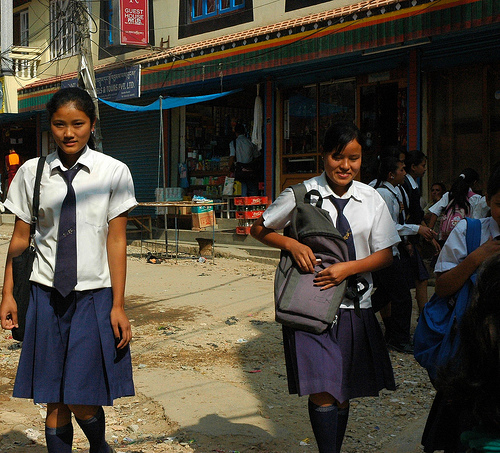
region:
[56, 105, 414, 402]
Children in school uniforms.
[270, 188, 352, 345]
Girl carrying her backpack.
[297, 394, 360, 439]
The girl is wearing blue socks.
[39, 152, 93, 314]
Girl is wearing a blue tie.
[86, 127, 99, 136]
The girl is wearing earring.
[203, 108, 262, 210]
A person standingin the store.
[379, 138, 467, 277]
A group of kids by the building.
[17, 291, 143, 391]
The skirt uniform is blue.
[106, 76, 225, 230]
An umbrella over the table.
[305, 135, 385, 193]
The girl is smiling.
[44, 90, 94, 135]
girl has dark hair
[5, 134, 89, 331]
black bag around shoulder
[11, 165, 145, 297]
girl has white shirt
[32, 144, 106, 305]
girl has blue tie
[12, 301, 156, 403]
girl has blue dress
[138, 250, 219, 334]
road is light brown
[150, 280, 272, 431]
road covered with dirt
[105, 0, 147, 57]
red and white sign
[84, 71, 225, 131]
blue tarp as awning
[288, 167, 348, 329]
girl has large grey bag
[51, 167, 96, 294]
The girl is wearing a blue tie.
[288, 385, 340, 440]
Girl wearing blue knee high socks.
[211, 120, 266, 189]
A person in the store.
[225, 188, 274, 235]
Soda racks on the ground.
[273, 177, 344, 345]
A blue backpack over the girl shoulder.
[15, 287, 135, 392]
The skirt is blue with plaits.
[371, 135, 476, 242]
A group of kids in front of the building.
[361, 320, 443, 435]
Rocks and trash on the ground.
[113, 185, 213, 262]
A table in front of the store.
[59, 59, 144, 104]
Blue sign hanging above the store.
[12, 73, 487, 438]
a crowd of female students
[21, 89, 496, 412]
a crowd of girls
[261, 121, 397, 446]
a girl wearing a blue and white outfit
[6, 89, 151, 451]
a girl wearing a blue and white outfit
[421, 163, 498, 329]
a girl wearing a blue and white outfit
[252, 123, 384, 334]
a girl opening a backpact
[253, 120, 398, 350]
a girl putting something in a backpack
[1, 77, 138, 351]
a girl with a black bag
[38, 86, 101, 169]
the head of a girl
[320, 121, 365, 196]
the head of a girl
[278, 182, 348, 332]
blue and black backpack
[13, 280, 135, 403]
a blue pleated skirt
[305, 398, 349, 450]
blue knee high socks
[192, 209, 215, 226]
a cardboard box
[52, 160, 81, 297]
a blue neck tie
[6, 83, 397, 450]
two girls walking in uniforms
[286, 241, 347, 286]
hands on the backpack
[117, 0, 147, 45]
a red business sign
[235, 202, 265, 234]
stack of bottled beverages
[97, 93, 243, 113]
a blue tarp for shade